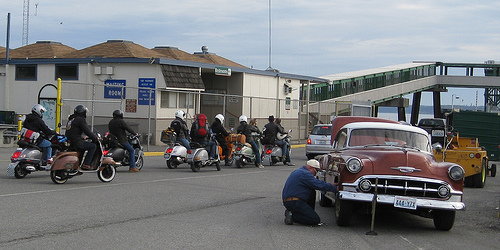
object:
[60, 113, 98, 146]
jacket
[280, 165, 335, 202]
shirt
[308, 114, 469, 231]
car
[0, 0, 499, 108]
sky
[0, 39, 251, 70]
roof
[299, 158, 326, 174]
cap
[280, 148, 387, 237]
repair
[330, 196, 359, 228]
tires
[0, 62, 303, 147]
walls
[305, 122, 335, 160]
car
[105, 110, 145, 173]
people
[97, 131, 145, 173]
bikes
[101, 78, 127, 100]
sign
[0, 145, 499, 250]
street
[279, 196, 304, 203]
belt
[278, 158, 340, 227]
man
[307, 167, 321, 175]
eyeglasses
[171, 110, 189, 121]
helmet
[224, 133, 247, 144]
bag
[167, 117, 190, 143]
jacket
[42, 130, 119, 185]
bike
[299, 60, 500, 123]
bridge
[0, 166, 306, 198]
line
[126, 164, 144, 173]
shoes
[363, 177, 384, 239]
jack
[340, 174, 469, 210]
bumper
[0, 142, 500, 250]
sidewalk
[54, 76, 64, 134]
pole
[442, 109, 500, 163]
metal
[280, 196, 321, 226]
jeans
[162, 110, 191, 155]
men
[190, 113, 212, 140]
backpack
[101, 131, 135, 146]
seat